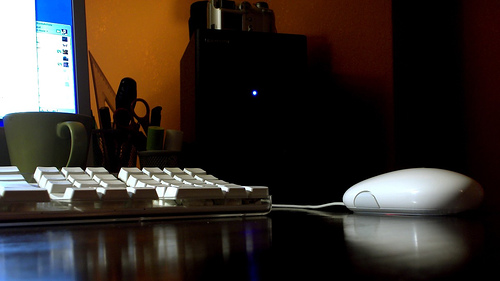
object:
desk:
[5, 164, 498, 279]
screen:
[0, 0, 100, 138]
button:
[352, 188, 381, 209]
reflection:
[343, 212, 470, 268]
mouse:
[337, 162, 486, 221]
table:
[2, 205, 499, 278]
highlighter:
[165, 128, 182, 148]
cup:
[138, 150, 174, 168]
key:
[126, 174, 152, 187]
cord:
[252, 198, 346, 210]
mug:
[0, 104, 95, 191]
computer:
[0, 0, 87, 163]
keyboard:
[1, 163, 271, 224]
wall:
[77, 2, 387, 182]